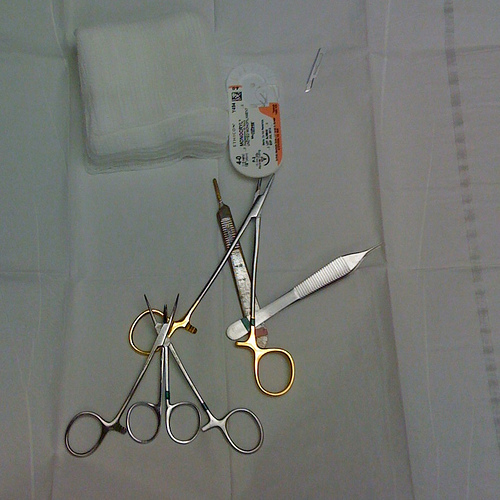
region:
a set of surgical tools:
[62, 173, 369, 458]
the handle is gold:
[130, 312, 294, 394]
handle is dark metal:
[65, 412, 124, 456]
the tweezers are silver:
[225, 245, 377, 340]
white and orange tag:
[225, 65, 285, 175]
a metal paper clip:
[303, 45, 320, 94]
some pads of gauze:
[74, 13, 231, 168]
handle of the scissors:
[128, 401, 196, 446]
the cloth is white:
[2, 2, 498, 499]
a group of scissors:
[30, 233, 345, 463]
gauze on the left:
[7, 15, 224, 159]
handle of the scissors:
[237, 346, 309, 402]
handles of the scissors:
[43, 406, 230, 461]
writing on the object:
[244, 63, 287, 185]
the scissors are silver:
[332, 256, 361, 296]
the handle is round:
[63, 408, 100, 455]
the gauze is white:
[105, 50, 185, 208]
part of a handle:
[265, 364, 291, 442]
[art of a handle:
[228, 407, 256, 452]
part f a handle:
[243, 333, 278, 426]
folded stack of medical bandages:
[61, 16, 238, 181]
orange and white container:
[223, 44, 292, 177]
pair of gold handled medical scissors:
[123, 154, 319, 405]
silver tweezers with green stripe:
[216, 221, 393, 358]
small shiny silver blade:
[296, 34, 346, 96]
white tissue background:
[1, 6, 491, 496]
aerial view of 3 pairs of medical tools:
[55, 174, 306, 499]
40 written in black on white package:
[233, 152, 244, 167]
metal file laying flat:
[201, 162, 266, 323]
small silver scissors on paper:
[160, 142, 340, 404]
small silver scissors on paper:
[142, 300, 259, 468]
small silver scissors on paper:
[72, 286, 176, 471]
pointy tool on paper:
[215, 167, 277, 354]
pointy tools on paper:
[35, 132, 406, 488]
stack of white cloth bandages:
[61, 17, 246, 214]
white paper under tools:
[22, 156, 95, 338]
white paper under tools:
[362, 80, 482, 218]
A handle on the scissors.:
[243, 343, 303, 394]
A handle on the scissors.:
[223, 402, 273, 450]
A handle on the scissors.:
[162, 401, 199, 441]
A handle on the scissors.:
[123, 400, 165, 445]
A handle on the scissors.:
[123, 301, 177, 360]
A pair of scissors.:
[57, 292, 268, 465]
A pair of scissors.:
[123, 300, 202, 446]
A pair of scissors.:
[177, 140, 341, 382]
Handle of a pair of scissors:
[123, 395, 203, 447]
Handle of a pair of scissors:
[128, 304, 294, 398]